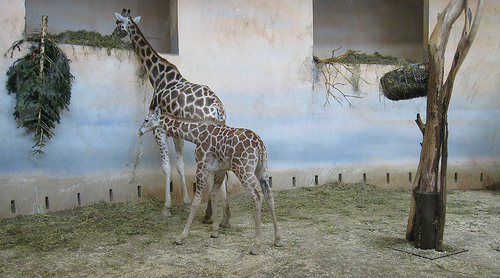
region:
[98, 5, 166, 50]
A giraffe is eating.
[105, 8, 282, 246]
Two giraffes are facing a wall.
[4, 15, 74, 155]
A green tree is upside down.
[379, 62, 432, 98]
A metal basket has straw in it.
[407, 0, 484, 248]
A dead tree has a fork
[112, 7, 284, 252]
Two giraffes are brown and white.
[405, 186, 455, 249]
A round black cylinder is by some wood.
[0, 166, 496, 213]
Vertical lines are near the ground.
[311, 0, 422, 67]
A window has straw in it.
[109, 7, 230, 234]
Mother giraffe in an enclosure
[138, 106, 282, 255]
Baby giraffe behind mother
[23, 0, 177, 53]
A high shelf in the wall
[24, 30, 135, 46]
The feed kept in the shelf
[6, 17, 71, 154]
A cut branch of a tree to feed the giraffes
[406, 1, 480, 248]
A dry dead tree in the enclosure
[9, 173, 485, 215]
Slits in a row near the bottom of a wall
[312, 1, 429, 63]
Another feeding ledge in the wall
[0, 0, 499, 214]
Old and faded blue wall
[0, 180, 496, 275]
Floor of the enclosure with grass fallen on it.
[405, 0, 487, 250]
The tree is brown.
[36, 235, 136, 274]
The ground is covered in hay.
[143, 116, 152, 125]
The giraffe eye is black.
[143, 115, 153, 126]
The giraffe eye is small.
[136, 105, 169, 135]
The giraffes face is white and brown.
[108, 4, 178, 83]
The giraffes neck is long.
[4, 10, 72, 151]
The tree is hanging upside down.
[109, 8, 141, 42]
The giraffe is eating hay.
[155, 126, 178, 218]
The giraffes leg is long.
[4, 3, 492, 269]
two giraffes standing inside an artificial habitat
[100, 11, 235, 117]
giraffe eating pile of hay from square opening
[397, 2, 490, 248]
dry tree standing in giraffe habitat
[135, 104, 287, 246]
small giraffe standing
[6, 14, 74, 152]
hanging tree branches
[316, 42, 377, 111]
hanging bare tree branches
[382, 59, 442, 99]
hay receptacle hanging from tree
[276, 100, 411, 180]
painted wall of giraffe habitat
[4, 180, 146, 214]
rectangle shaped holes in bottom of wall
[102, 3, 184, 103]
Giraffe feeding in a hopper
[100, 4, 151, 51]
giraffe head in the window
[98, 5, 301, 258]
two giraffes in a zoo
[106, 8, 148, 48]
giraffe head in the window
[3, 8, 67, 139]
tree branch hanging out the window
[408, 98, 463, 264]
Tree in the ground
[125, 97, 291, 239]
small giraffe near the wall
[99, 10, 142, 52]
giraffe head over the ledge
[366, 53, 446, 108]
feeder in the tree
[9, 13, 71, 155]
tree branch hanging on the wall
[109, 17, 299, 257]
two giraffes near the wall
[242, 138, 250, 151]
brown spot on giraffe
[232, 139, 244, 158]
brown spot on giraffe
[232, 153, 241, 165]
brown spot on giraffe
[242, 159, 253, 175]
brown spot on giraffe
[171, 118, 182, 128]
brown spot on giraffe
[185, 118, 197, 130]
brown spot on giraffe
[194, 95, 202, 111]
brown spot on giraffe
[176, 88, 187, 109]
brown spot on giraffe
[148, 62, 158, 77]
brown spot on giraffe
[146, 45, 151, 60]
brown spot on giraffe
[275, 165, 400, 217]
Pile of hay on ground.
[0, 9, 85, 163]
Small pine tree upside down on wall.